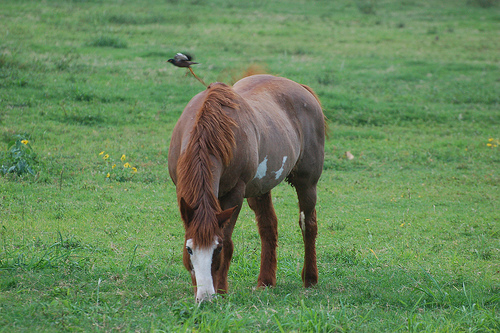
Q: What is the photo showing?
A: It is showing a field.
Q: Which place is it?
A: It is a field.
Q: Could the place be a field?
A: Yes, it is a field.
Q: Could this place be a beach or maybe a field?
A: It is a field.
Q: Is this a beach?
A: No, it is a field.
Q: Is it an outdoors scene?
A: Yes, it is outdoors.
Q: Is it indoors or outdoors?
A: It is outdoors.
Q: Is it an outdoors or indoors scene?
A: It is outdoors.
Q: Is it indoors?
A: No, it is outdoors.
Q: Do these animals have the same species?
A: No, they are horses and birds.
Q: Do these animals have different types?
A: Yes, they are horses and birds.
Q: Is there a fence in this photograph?
A: No, there are no fences.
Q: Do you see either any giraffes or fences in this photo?
A: No, there are no fences or giraffes.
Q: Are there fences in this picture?
A: No, there are no fences.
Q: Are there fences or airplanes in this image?
A: No, there are no fences or airplanes.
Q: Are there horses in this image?
A: Yes, there is a horse.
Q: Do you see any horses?
A: Yes, there is a horse.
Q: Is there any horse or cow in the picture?
A: Yes, there is a horse.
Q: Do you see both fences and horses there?
A: No, there is a horse but no fences.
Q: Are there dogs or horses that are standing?
A: Yes, the horse is standing.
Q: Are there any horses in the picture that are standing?
A: Yes, there is a horse that is standing.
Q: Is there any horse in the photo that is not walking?
A: Yes, there is a horse that is standing.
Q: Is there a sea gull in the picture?
A: No, there are no seagulls.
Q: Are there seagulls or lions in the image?
A: No, there are no seagulls or lions.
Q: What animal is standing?
A: The animal is a horse.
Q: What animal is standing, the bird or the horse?
A: The horse is standing.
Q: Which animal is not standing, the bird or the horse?
A: The bird is not standing.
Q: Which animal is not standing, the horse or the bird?
A: The bird is not standing.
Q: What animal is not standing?
A: The animal is a bird.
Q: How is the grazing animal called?
A: The animal is a horse.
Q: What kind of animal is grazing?
A: The animal is a horse.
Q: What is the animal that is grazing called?
A: The animal is a horse.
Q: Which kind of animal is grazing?
A: The animal is a horse.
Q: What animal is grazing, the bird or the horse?
A: The horse is grazing.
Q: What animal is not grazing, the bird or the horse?
A: The bird is not grazing.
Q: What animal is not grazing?
A: The animal is a bird.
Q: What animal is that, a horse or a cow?
A: That is a horse.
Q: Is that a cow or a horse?
A: That is a horse.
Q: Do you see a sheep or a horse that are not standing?
A: No, there is a horse but it is standing.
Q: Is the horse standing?
A: Yes, the horse is standing.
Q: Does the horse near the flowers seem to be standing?
A: Yes, the horse is standing.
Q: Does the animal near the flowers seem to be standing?
A: Yes, the horse is standing.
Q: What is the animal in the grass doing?
A: The horse is standing.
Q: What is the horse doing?
A: The horse is standing.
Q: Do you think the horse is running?
A: No, the horse is standing.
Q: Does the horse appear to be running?
A: No, the horse is standing.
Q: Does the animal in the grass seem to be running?
A: No, the horse is standing.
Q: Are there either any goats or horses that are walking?
A: No, there is a horse but it is standing.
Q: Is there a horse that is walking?
A: No, there is a horse but it is standing.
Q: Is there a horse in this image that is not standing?
A: No, there is a horse but it is standing.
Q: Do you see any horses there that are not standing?
A: No, there is a horse but it is standing.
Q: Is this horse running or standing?
A: The horse is standing.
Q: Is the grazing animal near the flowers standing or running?
A: The horse is standing.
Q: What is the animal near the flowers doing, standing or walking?
A: The horse is standing.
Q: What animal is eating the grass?
A: The horse is eating the grass.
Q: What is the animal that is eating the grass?
A: The animal is a horse.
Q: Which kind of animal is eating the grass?
A: The animal is a horse.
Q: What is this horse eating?
A: The horse is eating grass.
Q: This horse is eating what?
A: The horse is eating grass.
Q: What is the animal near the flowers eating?
A: The horse is eating grass.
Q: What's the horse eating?
A: The horse is eating grass.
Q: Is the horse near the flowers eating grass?
A: Yes, the horse is eating grass.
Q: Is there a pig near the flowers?
A: No, there is a horse near the flowers.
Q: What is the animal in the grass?
A: The animal is a horse.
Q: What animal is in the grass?
A: The animal is a horse.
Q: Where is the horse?
A: The horse is in the grass.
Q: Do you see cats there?
A: No, there are no cats.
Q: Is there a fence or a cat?
A: No, there are no cats or fences.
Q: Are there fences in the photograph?
A: No, there are no fences.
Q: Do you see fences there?
A: No, there are no fences.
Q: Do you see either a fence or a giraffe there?
A: No, there are no fences or giraffes.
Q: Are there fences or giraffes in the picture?
A: No, there are no fences or giraffes.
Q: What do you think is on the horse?
A: The spots are on the horse.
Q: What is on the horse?
A: The spots are on the horse.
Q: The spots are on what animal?
A: The spots are on the horse.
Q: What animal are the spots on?
A: The spots are on the horse.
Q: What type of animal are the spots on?
A: The spots are on the horse.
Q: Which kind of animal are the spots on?
A: The spots are on the horse.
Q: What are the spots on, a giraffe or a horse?
A: The spots are on a horse.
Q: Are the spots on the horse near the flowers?
A: Yes, the spots are on the horse.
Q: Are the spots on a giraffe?
A: No, the spots are on the horse.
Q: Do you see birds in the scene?
A: Yes, there is a bird.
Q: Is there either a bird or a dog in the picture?
A: Yes, there is a bird.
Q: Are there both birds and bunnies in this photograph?
A: No, there is a bird but no bunnies.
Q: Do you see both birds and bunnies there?
A: No, there is a bird but no bunnies.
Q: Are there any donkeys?
A: No, there are no donkeys.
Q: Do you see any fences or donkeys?
A: No, there are no donkeys or fences.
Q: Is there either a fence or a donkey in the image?
A: No, there are no donkeys or fences.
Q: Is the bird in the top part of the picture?
A: Yes, the bird is in the top of the image.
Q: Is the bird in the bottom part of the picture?
A: No, the bird is in the top of the image.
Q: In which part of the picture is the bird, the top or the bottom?
A: The bird is in the top of the image.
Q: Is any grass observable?
A: Yes, there is grass.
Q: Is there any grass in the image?
A: Yes, there is grass.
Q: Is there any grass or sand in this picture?
A: Yes, there is grass.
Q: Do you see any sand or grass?
A: Yes, there is grass.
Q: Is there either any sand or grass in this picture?
A: Yes, there is grass.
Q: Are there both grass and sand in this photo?
A: No, there is grass but no sand.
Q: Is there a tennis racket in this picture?
A: No, there are no rackets.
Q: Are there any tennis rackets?
A: No, there are no tennis rackets.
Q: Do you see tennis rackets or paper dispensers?
A: No, there are no tennis rackets or paper dispensers.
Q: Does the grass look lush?
A: Yes, the grass is lush.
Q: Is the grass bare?
A: No, the grass is lush.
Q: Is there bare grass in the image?
A: No, there is grass but it is lush.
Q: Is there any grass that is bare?
A: No, there is grass but it is lush.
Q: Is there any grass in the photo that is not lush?
A: No, there is grass but it is lush.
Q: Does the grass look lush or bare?
A: The grass is lush.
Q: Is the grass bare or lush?
A: The grass is lush.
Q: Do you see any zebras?
A: No, there are no zebras.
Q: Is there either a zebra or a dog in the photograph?
A: No, there are no zebras or dogs.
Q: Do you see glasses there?
A: No, there are no glasses.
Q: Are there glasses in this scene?
A: No, there are no glasses.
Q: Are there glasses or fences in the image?
A: No, there are no glasses or fences.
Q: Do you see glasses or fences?
A: No, there are no glasses or fences.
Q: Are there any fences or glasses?
A: No, there are no glasses or fences.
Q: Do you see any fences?
A: No, there are no fences.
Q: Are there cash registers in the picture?
A: No, there are no cash registers.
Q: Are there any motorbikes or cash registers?
A: No, there are no cash registers or motorbikes.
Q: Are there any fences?
A: No, there are no fences.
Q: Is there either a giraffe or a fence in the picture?
A: No, there are no fences or giraffes.